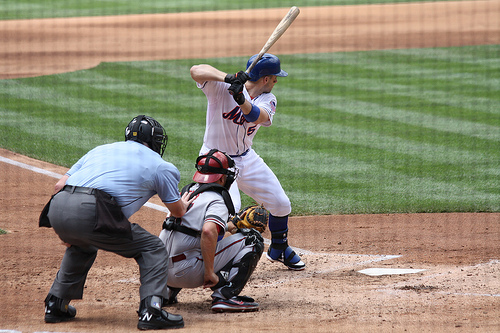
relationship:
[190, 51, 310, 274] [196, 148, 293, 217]
batter has pants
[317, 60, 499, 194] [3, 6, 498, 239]
grass on infield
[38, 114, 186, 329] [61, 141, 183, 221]
umpire has blue shirt